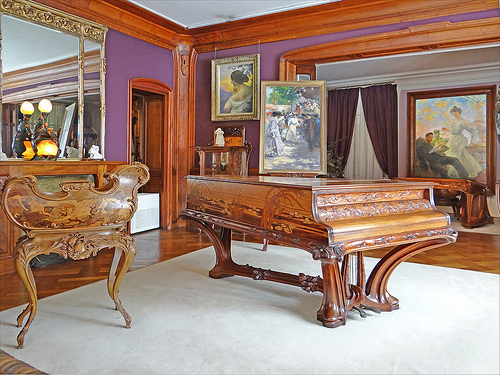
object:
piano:
[179, 173, 459, 329]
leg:
[316, 260, 349, 329]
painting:
[208, 53, 261, 123]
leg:
[112, 228, 136, 329]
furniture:
[0, 161, 150, 350]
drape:
[360, 84, 397, 178]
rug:
[1, 239, 500, 375]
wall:
[192, 8, 499, 217]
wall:
[104, 26, 176, 237]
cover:
[322, 210, 450, 245]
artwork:
[178, 174, 334, 254]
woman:
[223, 70, 253, 114]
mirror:
[0, 12, 104, 158]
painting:
[414, 93, 488, 187]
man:
[415, 132, 469, 180]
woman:
[441, 105, 483, 180]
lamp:
[30, 97, 62, 159]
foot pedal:
[353, 304, 369, 319]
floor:
[456, 232, 498, 275]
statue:
[86, 144, 104, 161]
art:
[257, 81, 328, 175]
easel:
[268, 171, 318, 178]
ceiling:
[130, 1, 340, 29]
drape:
[328, 86, 360, 178]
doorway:
[131, 87, 165, 233]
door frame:
[278, 17, 499, 80]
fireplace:
[20, 174, 99, 270]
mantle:
[0, 159, 129, 177]